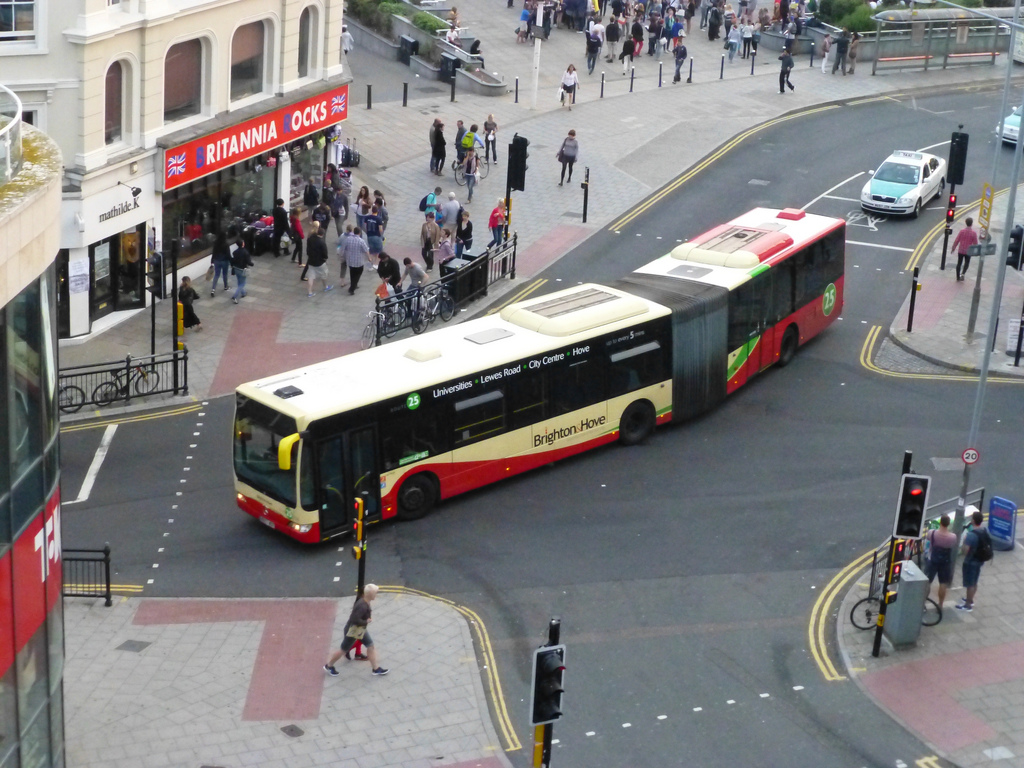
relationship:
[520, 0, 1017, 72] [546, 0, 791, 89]
crowd in street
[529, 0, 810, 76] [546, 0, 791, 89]
people in street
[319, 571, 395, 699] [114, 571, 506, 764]
person on sidewalk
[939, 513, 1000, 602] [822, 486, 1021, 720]
person on sidewalk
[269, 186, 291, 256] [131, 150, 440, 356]
person on sidewalk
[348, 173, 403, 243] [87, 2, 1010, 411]
person on sidewalk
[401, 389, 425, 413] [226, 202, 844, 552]
circle on front half of bus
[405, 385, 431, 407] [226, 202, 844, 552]
circle on back of bus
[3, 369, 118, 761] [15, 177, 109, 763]
wall on building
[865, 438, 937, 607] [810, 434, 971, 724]
light on corner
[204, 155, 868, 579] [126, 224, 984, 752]
bus on street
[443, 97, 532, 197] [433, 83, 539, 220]
person riding bike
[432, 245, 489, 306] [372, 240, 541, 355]
trashcans by fence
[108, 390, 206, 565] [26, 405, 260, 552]
line on road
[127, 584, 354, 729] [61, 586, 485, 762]
bricks on sidewalk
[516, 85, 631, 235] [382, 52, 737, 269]
person on sidewalk